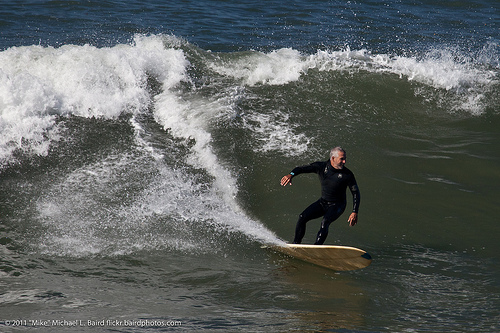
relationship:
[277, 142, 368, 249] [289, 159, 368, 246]
man wearing wetsuit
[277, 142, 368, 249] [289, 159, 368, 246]
man in wetsuit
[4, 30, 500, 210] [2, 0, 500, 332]
waves in ocean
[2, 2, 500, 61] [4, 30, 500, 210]
water beyond waves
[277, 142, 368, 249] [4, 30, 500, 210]
man conquers waves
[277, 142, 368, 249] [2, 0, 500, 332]
man in ocean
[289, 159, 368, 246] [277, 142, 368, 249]
wetsuit of man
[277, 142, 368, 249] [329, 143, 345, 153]
man has hair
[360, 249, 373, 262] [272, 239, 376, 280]
tip of surfboard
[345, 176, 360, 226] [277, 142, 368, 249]
arms away from man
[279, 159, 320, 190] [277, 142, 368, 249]
arms away from man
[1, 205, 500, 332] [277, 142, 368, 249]
water surrounding man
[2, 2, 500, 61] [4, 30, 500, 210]
water back of waves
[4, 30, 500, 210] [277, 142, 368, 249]
waves behind man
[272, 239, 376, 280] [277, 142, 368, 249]
surfboard under man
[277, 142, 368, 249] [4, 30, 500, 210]
man riding waves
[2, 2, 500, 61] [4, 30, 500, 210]
water behind waves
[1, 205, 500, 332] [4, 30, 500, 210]
water in front of waves